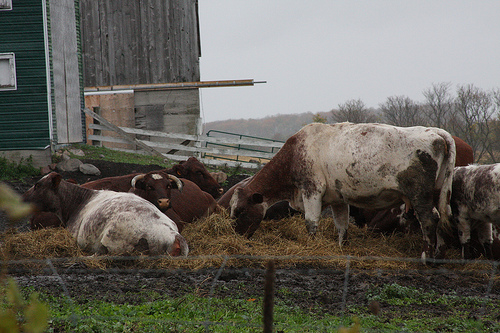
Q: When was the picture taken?
A: Daytime.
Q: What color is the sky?
A: Gray.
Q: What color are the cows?
A: White and brown.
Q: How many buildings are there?
A: One.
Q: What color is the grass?
A: Green.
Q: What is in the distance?
A: Trees.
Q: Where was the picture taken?
A: On a farm.